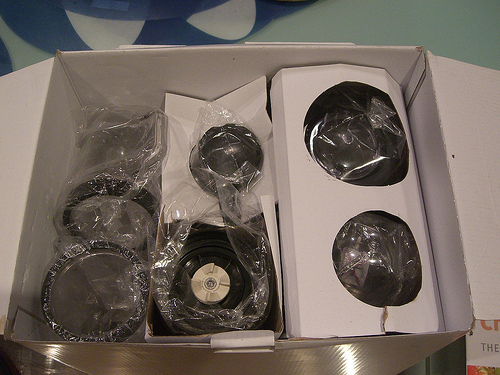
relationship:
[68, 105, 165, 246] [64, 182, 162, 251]
wrap around container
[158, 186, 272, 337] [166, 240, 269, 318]
plastic around blender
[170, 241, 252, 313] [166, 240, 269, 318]
ring on blender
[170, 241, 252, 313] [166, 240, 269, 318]
ring around blender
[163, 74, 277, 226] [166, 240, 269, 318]
cardboard around blender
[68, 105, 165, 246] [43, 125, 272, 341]
wrap around pieces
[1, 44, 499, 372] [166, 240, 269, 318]
box with blender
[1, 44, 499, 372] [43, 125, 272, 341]
box with pieces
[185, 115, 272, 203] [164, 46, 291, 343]
items in middle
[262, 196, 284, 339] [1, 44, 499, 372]
paper of box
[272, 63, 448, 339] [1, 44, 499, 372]
cover on box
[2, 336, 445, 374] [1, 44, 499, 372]
outside of box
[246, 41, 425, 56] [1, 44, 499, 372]
edge of box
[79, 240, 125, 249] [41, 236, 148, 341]
edge of wheel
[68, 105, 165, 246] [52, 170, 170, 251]
wrap over container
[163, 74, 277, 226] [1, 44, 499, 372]
cardboard in box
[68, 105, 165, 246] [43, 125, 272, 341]
wrap over pieces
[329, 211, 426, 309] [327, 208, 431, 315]
opening for bottom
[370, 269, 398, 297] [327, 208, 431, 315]
bottom of bottom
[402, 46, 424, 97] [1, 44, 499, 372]
corner of box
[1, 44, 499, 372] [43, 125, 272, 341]
box holding pieces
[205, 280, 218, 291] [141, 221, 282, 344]
center of blender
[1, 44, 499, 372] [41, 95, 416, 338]
box with parts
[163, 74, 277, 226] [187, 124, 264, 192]
cardboard with cutout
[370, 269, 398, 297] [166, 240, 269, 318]
bottom of blender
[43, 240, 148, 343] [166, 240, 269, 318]
cup for blender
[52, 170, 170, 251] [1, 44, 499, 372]
container in box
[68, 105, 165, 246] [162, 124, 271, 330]
wrap around items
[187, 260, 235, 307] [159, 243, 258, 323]
bottom on bottom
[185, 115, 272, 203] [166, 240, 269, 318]
items on blender